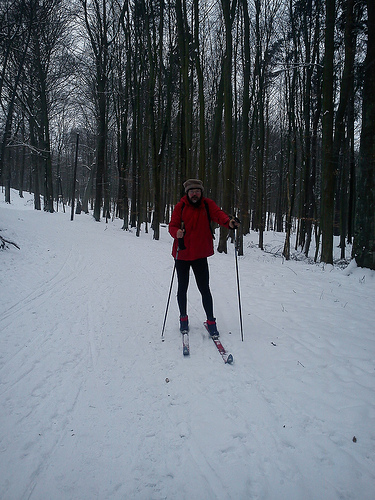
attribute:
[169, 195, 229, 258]
coat — red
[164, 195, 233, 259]
coat — red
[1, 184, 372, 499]
snow — white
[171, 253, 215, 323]
pants —  black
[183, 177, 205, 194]
cap — Brown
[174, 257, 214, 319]
tights — black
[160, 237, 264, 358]
pants — black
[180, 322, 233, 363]
skis — long, narrow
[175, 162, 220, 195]
beanie — brown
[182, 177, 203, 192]
hat — winter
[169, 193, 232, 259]
jacket — red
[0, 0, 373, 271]
trees — tall, bare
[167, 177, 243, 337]
man — wearing